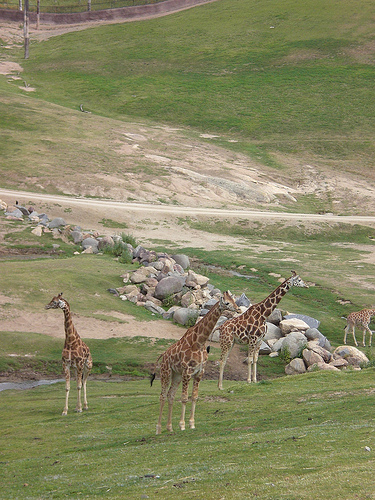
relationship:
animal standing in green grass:
[44, 292, 95, 414] [8, 4, 368, 495]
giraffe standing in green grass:
[343, 294, 373, 362] [8, 4, 368, 495]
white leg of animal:
[165, 411, 175, 436] [150, 286, 237, 438]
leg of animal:
[179, 402, 193, 433] [150, 286, 237, 438]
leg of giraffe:
[187, 395, 197, 430] [145, 290, 247, 440]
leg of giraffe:
[216, 360, 230, 392] [224, 277, 308, 383]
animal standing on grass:
[213, 267, 317, 392] [2, 353, 374, 498]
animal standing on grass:
[150, 286, 237, 438] [2, 353, 374, 498]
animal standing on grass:
[44, 292, 95, 414] [2, 353, 374, 498]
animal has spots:
[150, 286, 237, 438] [157, 307, 211, 386]